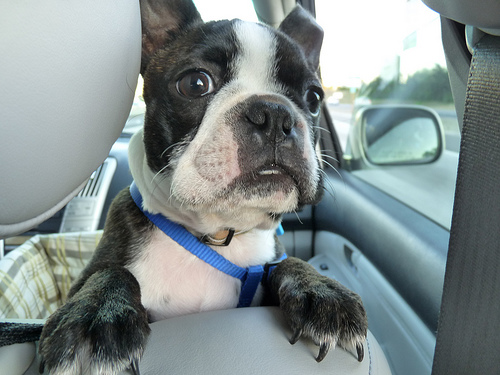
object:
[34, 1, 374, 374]
dog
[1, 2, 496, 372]
vehicle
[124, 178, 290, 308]
leash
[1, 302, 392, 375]
seat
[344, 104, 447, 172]
mirror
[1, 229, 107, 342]
basket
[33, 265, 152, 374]
leg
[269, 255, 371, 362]
leg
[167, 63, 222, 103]
eye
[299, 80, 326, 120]
eye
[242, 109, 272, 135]
nostril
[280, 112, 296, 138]
nostril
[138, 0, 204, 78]
ear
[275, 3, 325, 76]
ear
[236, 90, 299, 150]
nose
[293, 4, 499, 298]
side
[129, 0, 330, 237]
head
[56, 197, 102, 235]
control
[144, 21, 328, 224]
face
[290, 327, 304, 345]
claw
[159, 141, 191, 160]
whiskers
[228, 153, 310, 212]
mouth